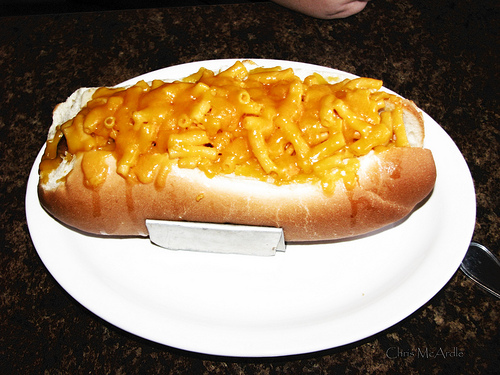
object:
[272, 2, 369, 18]
part of hand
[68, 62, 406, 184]
mac & cheese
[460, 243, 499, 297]
silverware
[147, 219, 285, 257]
holder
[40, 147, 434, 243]
bun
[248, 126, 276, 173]
macaroni piece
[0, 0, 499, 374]
table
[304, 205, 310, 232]
crack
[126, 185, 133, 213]
sauce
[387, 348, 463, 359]
name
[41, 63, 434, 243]
hot dog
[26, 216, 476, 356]
plate